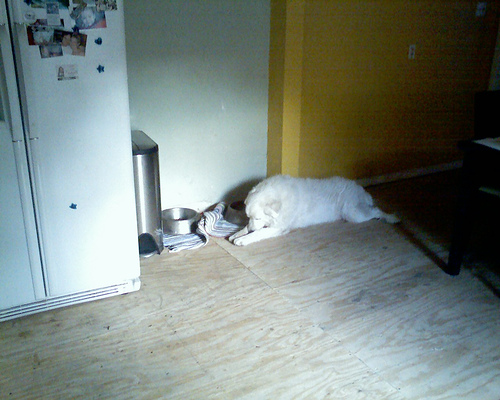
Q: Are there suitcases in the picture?
A: No, there are no suitcases.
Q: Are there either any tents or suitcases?
A: No, there are no suitcases or tents.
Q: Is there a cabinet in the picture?
A: No, there are no cabinets.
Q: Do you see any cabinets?
A: No, there are no cabinets.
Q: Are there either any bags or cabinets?
A: No, there are no cabinets or bags.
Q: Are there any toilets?
A: No, there are no toilets.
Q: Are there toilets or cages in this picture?
A: No, there are no toilets or cages.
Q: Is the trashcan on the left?
A: Yes, the trashcan is on the left of the image.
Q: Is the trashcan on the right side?
A: No, the trashcan is on the left of the image.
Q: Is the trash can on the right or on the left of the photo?
A: The trash can is on the left of the image.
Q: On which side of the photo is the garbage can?
A: The garbage can is on the left of the image.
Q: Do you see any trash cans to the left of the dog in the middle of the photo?
A: Yes, there is a trash can to the left of the dog.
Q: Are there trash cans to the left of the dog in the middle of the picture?
A: Yes, there is a trash can to the left of the dog.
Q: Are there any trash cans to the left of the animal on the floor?
A: Yes, there is a trash can to the left of the dog.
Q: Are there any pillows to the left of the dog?
A: No, there is a trash can to the left of the dog.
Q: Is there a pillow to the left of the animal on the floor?
A: No, there is a trash can to the left of the dog.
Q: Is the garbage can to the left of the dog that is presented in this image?
A: Yes, the garbage can is to the left of the dog.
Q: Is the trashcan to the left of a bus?
A: No, the trashcan is to the left of the dog.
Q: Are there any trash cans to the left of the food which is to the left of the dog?
A: Yes, there is a trash can to the left of the food.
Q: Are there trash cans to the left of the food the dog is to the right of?
A: Yes, there is a trash can to the left of the food.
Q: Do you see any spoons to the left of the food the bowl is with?
A: No, there is a trash can to the left of the food.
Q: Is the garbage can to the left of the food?
A: Yes, the garbage can is to the left of the food.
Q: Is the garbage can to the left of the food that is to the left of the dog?
A: Yes, the garbage can is to the left of the food.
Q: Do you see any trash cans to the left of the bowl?
A: Yes, there is a trash can to the left of the bowl.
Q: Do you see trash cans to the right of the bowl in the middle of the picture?
A: No, the trash can is to the left of the bowl.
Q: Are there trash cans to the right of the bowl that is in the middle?
A: No, the trash can is to the left of the bowl.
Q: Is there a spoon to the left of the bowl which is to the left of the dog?
A: No, there is a trash can to the left of the bowl.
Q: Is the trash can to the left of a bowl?
A: Yes, the trash can is to the left of a bowl.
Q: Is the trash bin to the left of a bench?
A: No, the trash bin is to the left of a bowl.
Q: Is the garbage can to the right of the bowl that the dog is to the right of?
A: No, the garbage can is to the left of the bowl.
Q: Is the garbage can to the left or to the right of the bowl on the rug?
A: The garbage can is to the left of the bowl.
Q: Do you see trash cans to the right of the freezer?
A: Yes, there is a trash can to the right of the freezer.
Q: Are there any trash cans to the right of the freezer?
A: Yes, there is a trash can to the right of the freezer.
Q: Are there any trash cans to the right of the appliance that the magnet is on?
A: Yes, there is a trash can to the right of the freezer.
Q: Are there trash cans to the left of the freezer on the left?
A: No, the trash can is to the right of the freezer.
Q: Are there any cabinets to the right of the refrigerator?
A: No, there is a trash can to the right of the refrigerator.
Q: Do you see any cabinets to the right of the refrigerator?
A: No, there is a trash can to the right of the refrigerator.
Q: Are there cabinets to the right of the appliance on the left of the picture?
A: No, there is a trash can to the right of the refrigerator.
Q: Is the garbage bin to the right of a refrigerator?
A: Yes, the garbage bin is to the right of a refrigerator.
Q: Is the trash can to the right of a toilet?
A: No, the trash can is to the right of a refrigerator.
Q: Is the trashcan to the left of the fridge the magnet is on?
A: No, the trashcan is to the right of the fridge.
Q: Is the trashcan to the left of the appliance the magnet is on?
A: No, the trashcan is to the right of the fridge.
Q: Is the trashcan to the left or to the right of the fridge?
A: The trashcan is to the right of the fridge.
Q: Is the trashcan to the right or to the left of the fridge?
A: The trashcan is to the right of the fridge.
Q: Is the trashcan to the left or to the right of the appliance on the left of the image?
A: The trashcan is to the right of the fridge.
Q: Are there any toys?
A: No, there are no toys.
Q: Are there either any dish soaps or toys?
A: No, there are no toys or dish soaps.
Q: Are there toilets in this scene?
A: No, there are no toilets.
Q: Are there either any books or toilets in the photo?
A: No, there are no toilets or books.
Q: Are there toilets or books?
A: No, there are no toilets or books.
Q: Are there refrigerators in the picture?
A: Yes, there is a refrigerator.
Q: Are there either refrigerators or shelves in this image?
A: Yes, there is a refrigerator.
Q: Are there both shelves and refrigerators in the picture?
A: No, there is a refrigerator but no shelves.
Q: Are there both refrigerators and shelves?
A: No, there is a refrigerator but no shelves.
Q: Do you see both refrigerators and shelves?
A: No, there is a refrigerator but no shelves.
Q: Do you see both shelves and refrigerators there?
A: No, there is a refrigerator but no shelves.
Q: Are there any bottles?
A: No, there are no bottles.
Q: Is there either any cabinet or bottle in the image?
A: No, there are no bottles or cabinets.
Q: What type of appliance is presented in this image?
A: The appliance is a refrigerator.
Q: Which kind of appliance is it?
A: The appliance is a refrigerator.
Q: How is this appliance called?
A: This is a refrigerator.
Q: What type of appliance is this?
A: This is a refrigerator.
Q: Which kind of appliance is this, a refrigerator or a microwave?
A: This is a refrigerator.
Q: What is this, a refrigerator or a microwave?
A: This is a refrigerator.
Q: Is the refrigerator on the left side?
A: Yes, the refrigerator is on the left of the image.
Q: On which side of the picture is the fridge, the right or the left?
A: The fridge is on the left of the image.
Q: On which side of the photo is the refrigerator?
A: The refrigerator is on the left of the image.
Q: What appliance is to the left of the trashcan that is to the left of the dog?
A: The appliance is a refrigerator.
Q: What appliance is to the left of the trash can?
A: The appliance is a refrigerator.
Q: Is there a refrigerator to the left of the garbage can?
A: Yes, there is a refrigerator to the left of the garbage can.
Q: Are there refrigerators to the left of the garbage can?
A: Yes, there is a refrigerator to the left of the garbage can.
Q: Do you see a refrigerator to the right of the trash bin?
A: No, the refrigerator is to the left of the trash bin.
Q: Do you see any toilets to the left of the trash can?
A: No, there is a refrigerator to the left of the trash can.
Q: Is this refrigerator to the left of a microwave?
A: No, the refrigerator is to the left of a trash can.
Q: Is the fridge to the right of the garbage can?
A: No, the fridge is to the left of the garbage can.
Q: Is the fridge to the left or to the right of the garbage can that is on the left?
A: The fridge is to the left of the trashcan.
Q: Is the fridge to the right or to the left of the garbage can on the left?
A: The fridge is to the left of the trashcan.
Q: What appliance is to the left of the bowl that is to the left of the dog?
A: The appliance is a refrigerator.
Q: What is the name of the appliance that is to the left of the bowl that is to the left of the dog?
A: The appliance is a refrigerator.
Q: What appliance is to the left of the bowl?
A: The appliance is a refrigerator.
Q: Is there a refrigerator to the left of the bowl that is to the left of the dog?
A: Yes, there is a refrigerator to the left of the bowl.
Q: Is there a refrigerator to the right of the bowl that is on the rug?
A: No, the refrigerator is to the left of the bowl.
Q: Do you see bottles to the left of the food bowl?
A: No, there is a refrigerator to the left of the bowl.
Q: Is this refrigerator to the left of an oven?
A: No, the refrigerator is to the left of a bowl.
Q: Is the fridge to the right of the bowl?
A: No, the fridge is to the left of the bowl.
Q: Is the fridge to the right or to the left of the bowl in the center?
A: The fridge is to the left of the bowl.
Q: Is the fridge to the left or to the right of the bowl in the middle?
A: The fridge is to the left of the bowl.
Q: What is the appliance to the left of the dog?
A: The appliance is a refrigerator.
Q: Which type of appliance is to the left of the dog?
A: The appliance is a refrigerator.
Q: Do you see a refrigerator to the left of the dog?
A: Yes, there is a refrigerator to the left of the dog.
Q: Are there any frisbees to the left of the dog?
A: No, there is a refrigerator to the left of the dog.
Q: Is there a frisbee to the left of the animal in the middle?
A: No, there is a refrigerator to the left of the dog.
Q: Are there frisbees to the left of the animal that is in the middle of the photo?
A: No, there is a refrigerator to the left of the dog.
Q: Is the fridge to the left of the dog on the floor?
A: Yes, the fridge is to the left of the dog.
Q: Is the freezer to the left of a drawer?
A: No, the freezer is to the left of the dog.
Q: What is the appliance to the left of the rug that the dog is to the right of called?
A: The appliance is a refrigerator.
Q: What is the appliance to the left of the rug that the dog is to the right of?
A: The appliance is a refrigerator.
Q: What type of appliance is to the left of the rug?
A: The appliance is a refrigerator.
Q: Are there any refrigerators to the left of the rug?
A: Yes, there is a refrigerator to the left of the rug.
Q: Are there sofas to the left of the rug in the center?
A: No, there is a refrigerator to the left of the rug.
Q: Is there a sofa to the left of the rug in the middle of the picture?
A: No, there is a refrigerator to the left of the rug.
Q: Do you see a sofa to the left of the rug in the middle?
A: No, there is a refrigerator to the left of the rug.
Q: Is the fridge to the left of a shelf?
A: No, the fridge is to the left of the rug.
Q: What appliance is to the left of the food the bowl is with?
A: The appliance is a refrigerator.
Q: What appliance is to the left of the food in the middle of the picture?
A: The appliance is a refrigerator.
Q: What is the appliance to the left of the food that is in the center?
A: The appliance is a refrigerator.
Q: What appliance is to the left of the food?
A: The appliance is a refrigerator.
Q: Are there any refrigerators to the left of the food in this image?
A: Yes, there is a refrigerator to the left of the food.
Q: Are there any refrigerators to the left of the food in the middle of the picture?
A: Yes, there is a refrigerator to the left of the food.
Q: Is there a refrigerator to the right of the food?
A: No, the refrigerator is to the left of the food.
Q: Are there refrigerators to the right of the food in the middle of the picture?
A: No, the refrigerator is to the left of the food.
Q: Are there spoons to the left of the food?
A: No, there is a refrigerator to the left of the food.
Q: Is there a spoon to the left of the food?
A: No, there is a refrigerator to the left of the food.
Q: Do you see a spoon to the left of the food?
A: No, there is a refrigerator to the left of the food.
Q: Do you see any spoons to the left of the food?
A: No, there is a refrigerator to the left of the food.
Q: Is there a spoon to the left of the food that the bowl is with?
A: No, there is a refrigerator to the left of the food.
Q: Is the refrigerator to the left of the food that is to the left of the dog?
A: Yes, the refrigerator is to the left of the food.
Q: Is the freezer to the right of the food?
A: No, the freezer is to the left of the food.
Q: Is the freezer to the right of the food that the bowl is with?
A: No, the freezer is to the left of the food.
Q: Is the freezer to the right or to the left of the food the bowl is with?
A: The freezer is to the left of the food.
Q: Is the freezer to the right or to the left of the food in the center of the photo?
A: The freezer is to the left of the food.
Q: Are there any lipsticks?
A: No, there are no lipsticks.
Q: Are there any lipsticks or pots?
A: No, there are no lipsticks or pots.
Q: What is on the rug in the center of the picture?
A: The bowl is on the rug.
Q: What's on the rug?
A: The bowl is on the rug.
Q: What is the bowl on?
A: The bowl is on the rug.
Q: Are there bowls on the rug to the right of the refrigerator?
A: Yes, there is a bowl on the rug.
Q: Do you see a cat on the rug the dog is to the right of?
A: No, there is a bowl on the rug.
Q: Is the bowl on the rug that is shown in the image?
A: Yes, the bowl is on the rug.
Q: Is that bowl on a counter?
A: No, the bowl is on the rug.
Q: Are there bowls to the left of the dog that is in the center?
A: Yes, there is a bowl to the left of the dog.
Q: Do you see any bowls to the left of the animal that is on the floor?
A: Yes, there is a bowl to the left of the dog.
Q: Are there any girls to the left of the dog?
A: No, there is a bowl to the left of the dog.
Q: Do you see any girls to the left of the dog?
A: No, there is a bowl to the left of the dog.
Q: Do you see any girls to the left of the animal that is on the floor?
A: No, there is a bowl to the left of the dog.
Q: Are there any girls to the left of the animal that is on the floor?
A: No, there is a bowl to the left of the dog.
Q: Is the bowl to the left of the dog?
A: Yes, the bowl is to the left of the dog.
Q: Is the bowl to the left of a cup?
A: No, the bowl is to the left of the dog.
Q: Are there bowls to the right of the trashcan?
A: Yes, there is a bowl to the right of the trashcan.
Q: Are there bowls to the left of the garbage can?
A: No, the bowl is to the right of the garbage can.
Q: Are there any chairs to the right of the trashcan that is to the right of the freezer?
A: No, there is a bowl to the right of the trashcan.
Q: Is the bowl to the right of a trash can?
A: Yes, the bowl is to the right of a trash can.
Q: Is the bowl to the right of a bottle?
A: No, the bowl is to the right of a trash can.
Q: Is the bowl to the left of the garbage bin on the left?
A: No, the bowl is to the right of the garbage bin.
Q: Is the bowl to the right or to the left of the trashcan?
A: The bowl is to the right of the trashcan.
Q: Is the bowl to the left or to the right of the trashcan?
A: The bowl is to the right of the trashcan.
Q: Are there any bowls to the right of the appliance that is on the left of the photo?
A: Yes, there is a bowl to the right of the freezer.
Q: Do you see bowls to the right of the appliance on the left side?
A: Yes, there is a bowl to the right of the freezer.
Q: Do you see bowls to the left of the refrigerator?
A: No, the bowl is to the right of the refrigerator.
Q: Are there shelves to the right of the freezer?
A: No, there is a bowl to the right of the freezer.